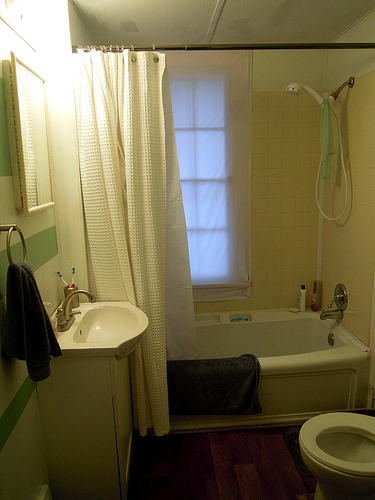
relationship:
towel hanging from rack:
[9, 261, 78, 367] [6, 225, 28, 267]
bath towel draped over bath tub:
[166, 353, 263, 416] [170, 307, 371, 433]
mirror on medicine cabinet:
[15, 61, 51, 211] [1, 47, 54, 216]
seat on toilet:
[300, 415, 373, 471] [298, 410, 374, 497]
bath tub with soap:
[195, 307, 371, 431] [231, 316, 248, 322]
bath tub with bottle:
[195, 307, 371, 431] [299, 283, 305, 311]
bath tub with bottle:
[195, 307, 371, 431] [310, 278, 319, 310]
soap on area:
[231, 316, 248, 322] [238, 303, 310, 321]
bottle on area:
[299, 283, 305, 311] [238, 303, 310, 321]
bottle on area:
[310, 278, 319, 310] [238, 303, 310, 321]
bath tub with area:
[195, 307, 371, 431] [238, 303, 310, 321]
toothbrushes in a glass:
[56, 270, 71, 289] [64, 286, 79, 307]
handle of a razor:
[228, 312, 244, 324] [226, 315, 251, 327]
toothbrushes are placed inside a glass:
[55, 266, 82, 286] [64, 286, 78, 304]